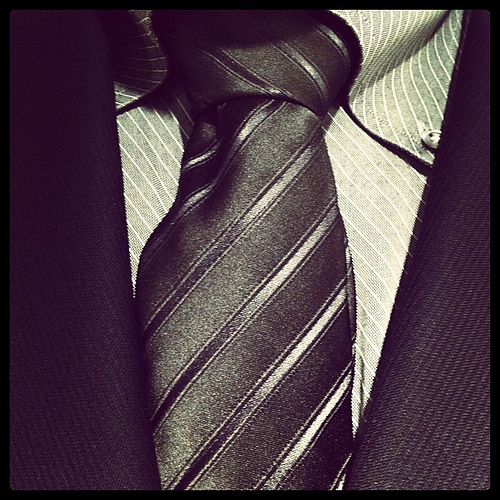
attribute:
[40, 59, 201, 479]
suit — classic, dark, black, present, here, formal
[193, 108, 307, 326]
tie — tied, shiny, dark, striped, present, here, black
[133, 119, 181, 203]
shirt — grey, striped, white, pin striped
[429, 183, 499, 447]
jacket — dark, black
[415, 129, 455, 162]
button — white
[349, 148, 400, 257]
stripes — thin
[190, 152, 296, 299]
lines — thick